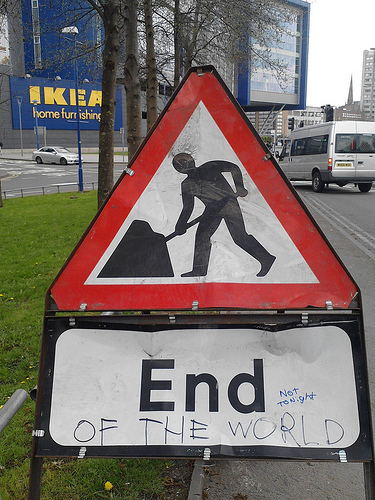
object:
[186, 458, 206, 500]
curb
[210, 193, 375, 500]
road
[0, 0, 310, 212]
trees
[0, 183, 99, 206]
railing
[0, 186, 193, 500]
grass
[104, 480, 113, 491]
flower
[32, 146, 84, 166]
car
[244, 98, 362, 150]
building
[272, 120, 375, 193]
car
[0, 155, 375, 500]
street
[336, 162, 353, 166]
license plate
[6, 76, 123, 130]
sign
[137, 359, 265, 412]
word end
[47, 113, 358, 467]
sign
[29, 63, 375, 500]
sign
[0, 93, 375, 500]
ground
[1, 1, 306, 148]
store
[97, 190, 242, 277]
shoveling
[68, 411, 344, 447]
words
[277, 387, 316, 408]
words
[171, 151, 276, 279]
figure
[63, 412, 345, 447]
graffiti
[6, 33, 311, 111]
building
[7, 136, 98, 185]
parked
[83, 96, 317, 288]
image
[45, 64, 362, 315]
triangular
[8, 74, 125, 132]
big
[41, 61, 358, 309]
center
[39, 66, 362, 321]
border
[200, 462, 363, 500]
cement